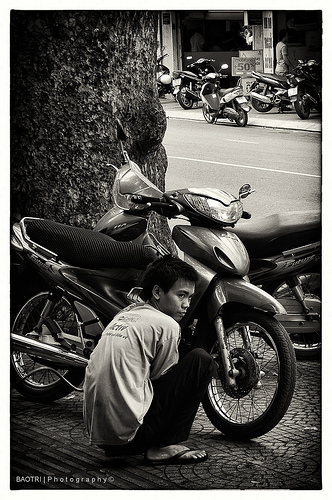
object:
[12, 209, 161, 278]
seat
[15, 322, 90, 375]
pipe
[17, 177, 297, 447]
motorcycle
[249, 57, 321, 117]
motorcycles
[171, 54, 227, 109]
motorcycles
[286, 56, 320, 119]
motorcycles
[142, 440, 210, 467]
flip flops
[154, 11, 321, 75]
building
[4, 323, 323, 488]
sidewalk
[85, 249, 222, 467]
man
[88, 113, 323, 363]
bike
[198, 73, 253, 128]
bike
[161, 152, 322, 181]
line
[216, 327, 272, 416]
spokes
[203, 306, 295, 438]
tire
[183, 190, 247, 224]
front light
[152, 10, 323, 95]
shop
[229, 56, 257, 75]
sign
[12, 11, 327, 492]
scene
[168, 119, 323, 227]
road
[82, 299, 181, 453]
shirt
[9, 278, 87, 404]
wheels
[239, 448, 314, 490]
bricks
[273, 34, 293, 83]
woman